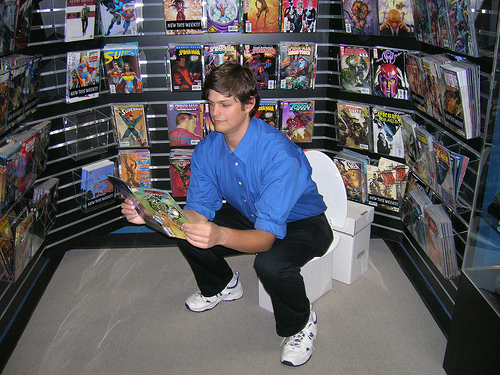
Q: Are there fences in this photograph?
A: No, there are no fences.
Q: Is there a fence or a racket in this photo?
A: No, there are no fences or rackets.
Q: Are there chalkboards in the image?
A: No, there are no chalkboards.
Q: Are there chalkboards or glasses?
A: No, there are no chalkboards or glasses.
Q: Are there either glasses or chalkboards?
A: No, there are no chalkboards or glasses.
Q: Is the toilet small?
A: Yes, the toilet is small.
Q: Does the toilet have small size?
A: Yes, the toilet is small.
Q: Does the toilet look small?
A: Yes, the toilet is small.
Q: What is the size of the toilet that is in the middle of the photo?
A: The toilet is small.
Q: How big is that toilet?
A: The toilet is small.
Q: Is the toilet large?
A: No, the toilet is small.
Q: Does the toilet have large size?
A: No, the toilet is small.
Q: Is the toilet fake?
A: Yes, the toilet is fake.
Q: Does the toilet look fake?
A: Yes, the toilet is fake.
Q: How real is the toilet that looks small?
A: The toilet is fake.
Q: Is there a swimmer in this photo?
A: No, there are no swimmers.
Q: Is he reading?
A: Yes, the man is reading.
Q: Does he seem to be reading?
A: Yes, the man is reading.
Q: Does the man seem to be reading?
A: Yes, the man is reading.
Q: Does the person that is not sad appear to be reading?
A: Yes, the man is reading.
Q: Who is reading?
A: The man is reading.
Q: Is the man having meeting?
A: No, the man is reading.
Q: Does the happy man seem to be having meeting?
A: No, the man is reading.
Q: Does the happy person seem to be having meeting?
A: No, the man is reading.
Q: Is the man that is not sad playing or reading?
A: The man is reading.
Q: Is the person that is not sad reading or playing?
A: The man is reading.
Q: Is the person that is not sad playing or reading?
A: The man is reading.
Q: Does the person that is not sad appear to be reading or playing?
A: The man is reading.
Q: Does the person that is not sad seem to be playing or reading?
A: The man is reading.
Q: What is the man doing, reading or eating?
A: The man is reading.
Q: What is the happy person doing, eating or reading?
A: The man is reading.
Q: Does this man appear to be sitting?
A: Yes, the man is sitting.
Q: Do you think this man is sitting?
A: Yes, the man is sitting.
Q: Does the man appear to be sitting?
A: Yes, the man is sitting.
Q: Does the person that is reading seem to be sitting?
A: Yes, the man is sitting.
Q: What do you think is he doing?
A: The man is sitting.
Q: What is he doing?
A: The man is sitting.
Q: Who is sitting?
A: The man is sitting.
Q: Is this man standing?
A: No, the man is sitting.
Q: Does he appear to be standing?
A: No, the man is sitting.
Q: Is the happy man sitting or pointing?
A: The man is sitting.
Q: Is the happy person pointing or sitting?
A: The man is sitting.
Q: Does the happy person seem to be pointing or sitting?
A: The man is sitting.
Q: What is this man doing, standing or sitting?
A: The man is sitting.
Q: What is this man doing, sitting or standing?
A: The man is sitting.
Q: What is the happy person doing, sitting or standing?
A: The man is sitting.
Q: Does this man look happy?
A: Yes, the man is happy.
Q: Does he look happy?
A: Yes, the man is happy.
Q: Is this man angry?
A: No, the man is happy.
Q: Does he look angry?
A: No, the man is happy.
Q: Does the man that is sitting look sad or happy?
A: The man is happy.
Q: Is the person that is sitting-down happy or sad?
A: The man is happy.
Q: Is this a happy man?
A: Yes, this is a happy man.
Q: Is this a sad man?
A: No, this is a happy man.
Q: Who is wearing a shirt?
A: The man is wearing a shirt.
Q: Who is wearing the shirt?
A: The man is wearing a shirt.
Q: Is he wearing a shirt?
A: Yes, the man is wearing a shirt.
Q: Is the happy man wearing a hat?
A: No, the man is wearing a shirt.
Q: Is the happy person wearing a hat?
A: No, the man is wearing a shirt.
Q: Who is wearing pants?
A: The man is wearing pants.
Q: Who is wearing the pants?
A: The man is wearing pants.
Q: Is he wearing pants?
A: Yes, the man is wearing pants.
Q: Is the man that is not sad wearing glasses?
A: No, the man is wearing pants.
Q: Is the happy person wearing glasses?
A: No, the man is wearing pants.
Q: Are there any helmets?
A: No, there are no helmets.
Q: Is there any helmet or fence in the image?
A: No, there are no helmets or fences.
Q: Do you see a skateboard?
A: No, there are no skateboards.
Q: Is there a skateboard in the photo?
A: No, there are no skateboards.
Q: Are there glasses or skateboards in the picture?
A: No, there are no skateboards or glasses.